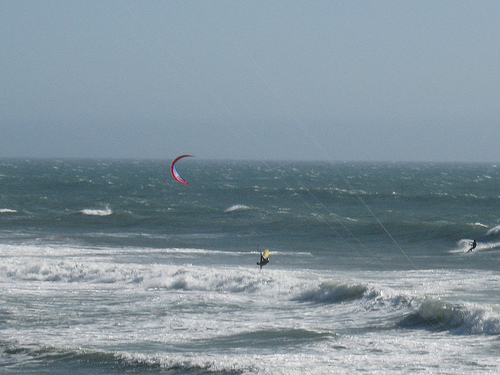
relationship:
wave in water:
[58, 203, 142, 230] [0, 158, 498, 373]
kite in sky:
[171, 155, 196, 186] [0, 0, 498, 169]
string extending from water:
[114, 0, 500, 375] [0, 158, 498, 373]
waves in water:
[277, 276, 483, 324] [1, 160, 498, 350]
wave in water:
[69, 205, 133, 220] [0, 158, 498, 373]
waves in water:
[277, 276, 483, 324] [0, 158, 498, 373]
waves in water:
[123, 345, 250, 371] [0, 158, 498, 373]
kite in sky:
[167, 147, 208, 195] [58, 65, 303, 148]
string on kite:
[266, 127, 413, 287] [168, 150, 197, 187]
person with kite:
[257, 247, 271, 265] [164, 147, 204, 195]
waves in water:
[277, 276, 483, 324] [249, 191, 449, 266]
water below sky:
[0, 158, 498, 373] [0, 0, 498, 169]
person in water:
[246, 233, 482, 271] [7, 138, 488, 370]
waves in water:
[277, 276, 483, 324] [17, 114, 467, 353]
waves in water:
[123, 345, 250, 371] [59, 112, 448, 358]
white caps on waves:
[35, 151, 148, 202] [53, 223, 496, 347]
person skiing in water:
[465, 234, 479, 253] [0, 158, 498, 373]